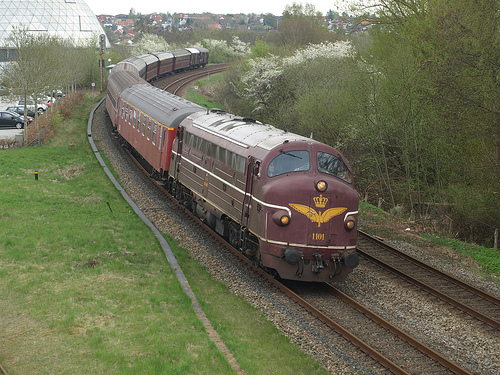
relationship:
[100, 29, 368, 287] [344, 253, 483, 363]
train on tracks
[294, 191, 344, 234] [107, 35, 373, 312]
wings on train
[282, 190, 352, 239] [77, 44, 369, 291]
crown on train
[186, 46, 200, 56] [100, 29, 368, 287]
roof on train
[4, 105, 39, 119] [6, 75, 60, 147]
cars parked lot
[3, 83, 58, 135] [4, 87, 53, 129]
cars parked lot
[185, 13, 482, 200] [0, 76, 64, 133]
trees of cars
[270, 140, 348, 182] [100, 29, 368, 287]
window of train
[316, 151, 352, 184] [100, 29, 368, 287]
window of train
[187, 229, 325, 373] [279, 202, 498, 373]
grass beside tracks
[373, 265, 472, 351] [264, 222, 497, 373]
stone in railways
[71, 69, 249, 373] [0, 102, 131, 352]
steel on grass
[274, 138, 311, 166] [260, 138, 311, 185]
wiper at top glass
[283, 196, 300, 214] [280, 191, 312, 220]
tip of wing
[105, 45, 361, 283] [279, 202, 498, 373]
train travelling down tracks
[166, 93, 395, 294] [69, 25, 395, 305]
locomotive of train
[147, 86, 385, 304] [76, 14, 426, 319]
engine of train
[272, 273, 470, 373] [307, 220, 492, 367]
rails of track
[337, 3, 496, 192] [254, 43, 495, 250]
foliage of trees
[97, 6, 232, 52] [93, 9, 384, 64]
houses on hillside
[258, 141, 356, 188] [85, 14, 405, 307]
windshield on train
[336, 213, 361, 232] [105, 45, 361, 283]
headlight on train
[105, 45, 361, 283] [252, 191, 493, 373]
train on track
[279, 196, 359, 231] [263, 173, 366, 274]
symbol on front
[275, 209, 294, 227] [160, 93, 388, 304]
light on train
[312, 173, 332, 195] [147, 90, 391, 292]
light on train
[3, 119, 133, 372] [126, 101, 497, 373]
grass by track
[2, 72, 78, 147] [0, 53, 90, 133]
cars in lot